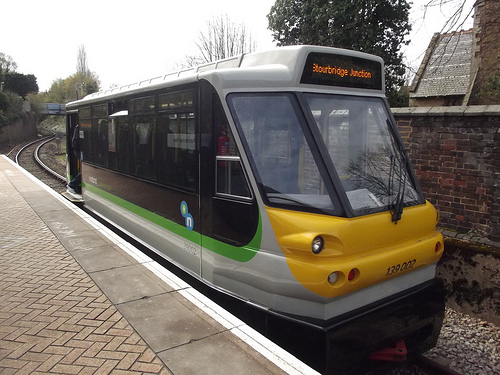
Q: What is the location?
A: Train track.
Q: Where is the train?
A: On the tracks.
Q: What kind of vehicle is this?
A: Train.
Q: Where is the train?
A: Train tracks.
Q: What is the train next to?
A: Platform.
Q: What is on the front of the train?
A: Digital window.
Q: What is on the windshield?
A: Windshield wipers.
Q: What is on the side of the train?
A: Green stripe.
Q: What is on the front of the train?
A: Numbers in black print.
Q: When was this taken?
A: Daytime.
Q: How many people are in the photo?
A: 0.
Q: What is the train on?
A: Train tracks.